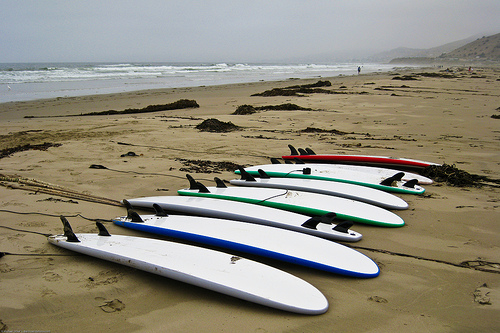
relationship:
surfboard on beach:
[284, 143, 452, 168] [1, 68, 499, 330]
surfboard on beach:
[236, 154, 425, 197] [1, 68, 499, 330]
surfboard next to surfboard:
[232, 167, 409, 215] [236, 154, 425, 197]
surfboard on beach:
[179, 173, 404, 235] [1, 68, 499, 330]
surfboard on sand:
[115, 200, 381, 288] [1, 68, 499, 330]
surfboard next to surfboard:
[48, 216, 329, 318] [115, 200, 381, 288]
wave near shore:
[0, 61, 275, 78] [1, 66, 445, 132]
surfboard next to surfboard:
[115, 200, 381, 288] [48, 216, 329, 318]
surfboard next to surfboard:
[115, 200, 381, 288] [121, 188, 363, 248]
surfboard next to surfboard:
[121, 188, 363, 248] [179, 173, 404, 235]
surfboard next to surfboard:
[232, 167, 409, 215] [179, 173, 404, 235]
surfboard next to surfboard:
[236, 154, 425, 197] [232, 167, 409, 215]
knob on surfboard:
[95, 219, 110, 236] [48, 216, 329, 318]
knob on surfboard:
[63, 226, 80, 242] [48, 216, 329, 318]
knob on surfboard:
[58, 215, 69, 227] [48, 216, 329, 318]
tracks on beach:
[0, 174, 125, 212] [1, 68, 499, 330]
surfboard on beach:
[232, 167, 409, 215] [1, 68, 499, 330]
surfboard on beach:
[121, 188, 363, 248] [1, 68, 499, 330]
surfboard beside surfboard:
[284, 143, 452, 168] [236, 154, 425, 197]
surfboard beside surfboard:
[232, 167, 409, 215] [236, 154, 425, 197]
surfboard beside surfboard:
[179, 173, 404, 235] [232, 167, 409, 215]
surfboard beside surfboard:
[121, 188, 363, 248] [179, 173, 404, 235]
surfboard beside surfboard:
[115, 200, 381, 288] [121, 188, 363, 248]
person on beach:
[355, 66, 361, 74] [1, 68, 499, 330]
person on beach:
[466, 66, 473, 72] [1, 68, 499, 330]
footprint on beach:
[45, 270, 61, 283] [1, 68, 499, 330]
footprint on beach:
[24, 244, 44, 255] [1, 68, 499, 330]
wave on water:
[211, 62, 349, 73] [3, 62, 422, 103]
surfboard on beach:
[48, 216, 329, 318] [1, 68, 499, 330]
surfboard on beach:
[115, 200, 381, 288] [1, 68, 499, 330]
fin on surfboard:
[305, 147, 316, 155] [284, 143, 452, 168]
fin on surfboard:
[299, 147, 310, 157] [284, 143, 452, 168]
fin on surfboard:
[287, 143, 299, 156] [284, 143, 452, 168]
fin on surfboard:
[126, 209, 142, 223] [115, 200, 381, 288]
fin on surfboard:
[152, 203, 168, 217] [115, 200, 381, 288]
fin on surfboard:
[124, 199, 132, 215] [115, 200, 381, 288]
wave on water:
[0, 61, 275, 78] [3, 62, 422, 103]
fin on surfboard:
[195, 180, 209, 193] [179, 173, 404, 235]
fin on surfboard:
[214, 176, 225, 188] [179, 173, 404, 235]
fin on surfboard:
[183, 172, 199, 189] [179, 173, 404, 235]